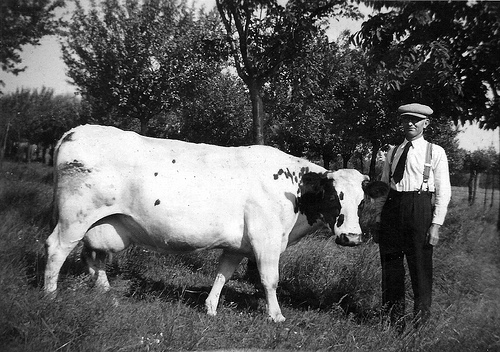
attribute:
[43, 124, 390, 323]
cow — black, white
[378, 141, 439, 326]
suspenders — brown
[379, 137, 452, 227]
shirt — white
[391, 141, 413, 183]
tie — black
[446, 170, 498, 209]
fence — here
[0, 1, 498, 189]
trees — here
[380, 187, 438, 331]
pants — black